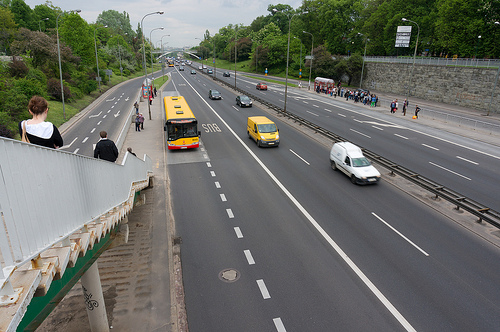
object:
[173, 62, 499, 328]
lane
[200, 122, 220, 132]
word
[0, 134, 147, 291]
rail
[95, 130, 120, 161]
male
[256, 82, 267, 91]
car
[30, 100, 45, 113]
hair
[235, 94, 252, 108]
cars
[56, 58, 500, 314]
highway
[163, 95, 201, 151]
bus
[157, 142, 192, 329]
curb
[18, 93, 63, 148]
female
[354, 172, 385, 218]
ground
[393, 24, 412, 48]
banner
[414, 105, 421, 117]
people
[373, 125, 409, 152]
ground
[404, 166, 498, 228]
guardrail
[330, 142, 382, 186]
car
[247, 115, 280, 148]
car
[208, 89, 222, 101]
car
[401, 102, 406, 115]
people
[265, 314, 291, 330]
dotted line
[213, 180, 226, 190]
line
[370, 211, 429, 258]
line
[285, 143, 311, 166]
line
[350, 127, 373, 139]
line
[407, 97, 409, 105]
person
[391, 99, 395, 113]
person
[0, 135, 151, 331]
stairway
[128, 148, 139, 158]
person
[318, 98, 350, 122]
ground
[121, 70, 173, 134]
bus stop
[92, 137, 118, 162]
black outerwear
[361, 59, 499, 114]
wall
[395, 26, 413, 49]
sign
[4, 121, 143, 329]
steps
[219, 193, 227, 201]
lines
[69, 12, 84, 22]
street lights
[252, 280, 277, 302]
line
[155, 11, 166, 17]
light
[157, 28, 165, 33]
light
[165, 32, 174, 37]
light